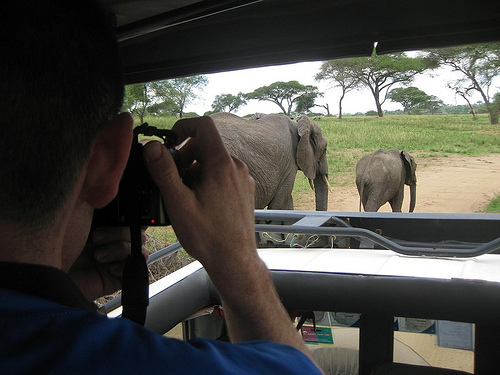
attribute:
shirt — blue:
[8, 257, 328, 373]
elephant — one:
[354, 146, 428, 211]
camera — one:
[115, 138, 215, 235]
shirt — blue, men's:
[17, 271, 319, 371]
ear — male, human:
[84, 105, 144, 216]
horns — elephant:
[302, 168, 340, 199]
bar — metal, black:
[291, 221, 498, 265]